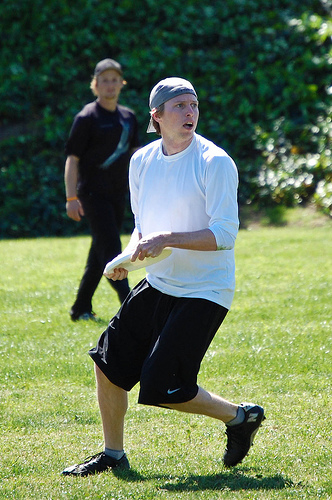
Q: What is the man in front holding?
A: A Frisbee.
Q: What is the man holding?
A: Frisbee.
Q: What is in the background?
A: Trees.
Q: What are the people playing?
A: Frisbee.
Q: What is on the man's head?
A: Hat.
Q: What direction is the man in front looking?
A: Right.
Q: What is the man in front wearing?
A: White shirt and black shorts.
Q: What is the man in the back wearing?
A: Black shirt and black pants.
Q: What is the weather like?
A: Sunny.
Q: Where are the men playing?
A: In the grass.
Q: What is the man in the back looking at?
A: The guy with the frisbee.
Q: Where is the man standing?
A: In a field of green grass.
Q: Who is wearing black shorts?
A: The man.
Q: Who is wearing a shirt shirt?
A: The man.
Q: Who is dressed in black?
A: A boy.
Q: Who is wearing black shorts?
A: The frisbee player.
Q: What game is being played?
A: Frisbee.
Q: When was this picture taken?
A: Daytime.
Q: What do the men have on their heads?
A: Hats.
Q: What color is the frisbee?
A: White.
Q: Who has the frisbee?
A: Man in white.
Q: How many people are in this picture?
A: 2.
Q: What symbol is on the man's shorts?
A: Nike.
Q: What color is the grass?
A: Green.